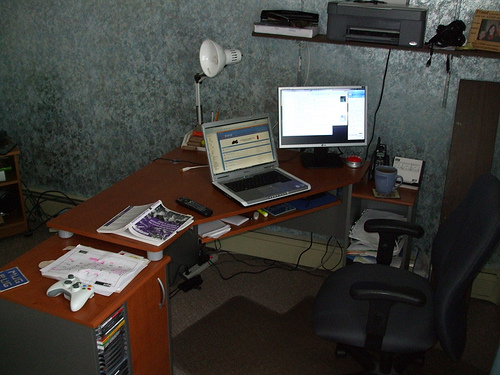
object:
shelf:
[245, 0, 500, 60]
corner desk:
[48, 139, 425, 372]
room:
[0, 0, 500, 374]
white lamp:
[182, 36, 244, 155]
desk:
[1, 136, 498, 372]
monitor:
[275, 82, 380, 153]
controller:
[47, 275, 97, 313]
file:
[0, 233, 176, 374]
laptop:
[201, 112, 313, 211]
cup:
[372, 165, 401, 197]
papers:
[348, 206, 404, 245]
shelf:
[344, 247, 417, 274]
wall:
[0, 0, 500, 276]